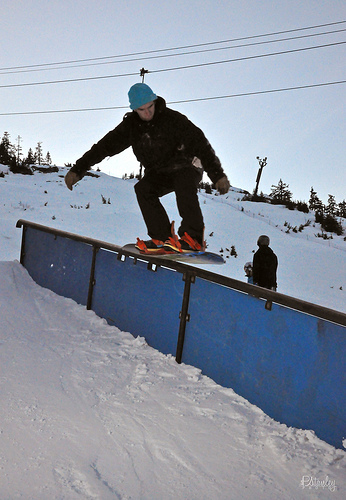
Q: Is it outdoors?
A: Yes, it is outdoors.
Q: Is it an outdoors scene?
A: Yes, it is outdoors.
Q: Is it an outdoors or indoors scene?
A: It is outdoors.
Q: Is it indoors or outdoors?
A: It is outdoors.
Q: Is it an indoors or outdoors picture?
A: It is outdoors.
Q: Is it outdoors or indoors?
A: It is outdoors.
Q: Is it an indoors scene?
A: No, it is outdoors.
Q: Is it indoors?
A: No, it is outdoors.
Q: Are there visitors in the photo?
A: No, there are no visitors.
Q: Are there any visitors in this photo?
A: No, there are no visitors.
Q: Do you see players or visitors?
A: No, there are no visitors or players.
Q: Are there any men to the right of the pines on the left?
A: Yes, there is a man to the right of the pines.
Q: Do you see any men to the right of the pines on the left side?
A: Yes, there is a man to the right of the pines.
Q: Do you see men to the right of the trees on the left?
A: Yes, there is a man to the right of the pines.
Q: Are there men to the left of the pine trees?
A: No, the man is to the right of the pine trees.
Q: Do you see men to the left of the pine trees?
A: No, the man is to the right of the pine trees.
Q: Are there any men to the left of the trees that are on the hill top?
A: No, the man is to the right of the pine trees.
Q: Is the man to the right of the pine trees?
A: Yes, the man is to the right of the pine trees.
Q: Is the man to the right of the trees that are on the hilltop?
A: Yes, the man is to the right of the pine trees.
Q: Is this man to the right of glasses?
A: No, the man is to the right of the pine trees.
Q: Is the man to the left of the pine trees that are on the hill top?
A: No, the man is to the right of the pine trees.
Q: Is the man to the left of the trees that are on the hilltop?
A: No, the man is to the right of the pine trees.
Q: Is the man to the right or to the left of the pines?
A: The man is to the right of the pines.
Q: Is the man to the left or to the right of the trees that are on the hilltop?
A: The man is to the right of the pines.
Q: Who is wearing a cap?
A: The man is wearing a cap.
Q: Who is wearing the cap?
A: The man is wearing a cap.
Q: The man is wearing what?
A: The man is wearing a cap.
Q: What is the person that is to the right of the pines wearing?
A: The man is wearing a cap.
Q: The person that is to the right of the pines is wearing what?
A: The man is wearing a cap.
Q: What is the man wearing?
A: The man is wearing a cap.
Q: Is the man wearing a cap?
A: Yes, the man is wearing a cap.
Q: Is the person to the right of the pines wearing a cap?
A: Yes, the man is wearing a cap.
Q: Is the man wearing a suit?
A: No, the man is wearing a cap.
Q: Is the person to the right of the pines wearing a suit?
A: No, the man is wearing a cap.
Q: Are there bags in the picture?
A: No, there are no bags.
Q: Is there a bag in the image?
A: No, there are no bags.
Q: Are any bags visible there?
A: No, there are no bags.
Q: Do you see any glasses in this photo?
A: No, there are no glasses.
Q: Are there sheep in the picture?
A: No, there are no sheep.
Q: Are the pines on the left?
A: Yes, the pines are on the left of the image.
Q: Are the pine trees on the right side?
A: No, the pine trees are on the left of the image.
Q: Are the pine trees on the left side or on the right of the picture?
A: The pine trees are on the left of the image.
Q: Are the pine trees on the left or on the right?
A: The pine trees are on the left of the image.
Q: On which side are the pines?
A: The pines are on the left of the image.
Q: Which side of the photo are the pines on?
A: The pines are on the left of the image.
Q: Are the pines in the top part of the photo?
A: Yes, the pines are in the top of the image.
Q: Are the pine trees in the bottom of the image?
A: No, the pine trees are in the top of the image.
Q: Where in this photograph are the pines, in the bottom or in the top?
A: The pines are in the top of the image.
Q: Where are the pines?
A: The pines are on the hilltop.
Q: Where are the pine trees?
A: The pines are on the hilltop.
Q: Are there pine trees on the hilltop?
A: Yes, there are pine trees on the hilltop.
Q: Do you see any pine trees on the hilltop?
A: Yes, there are pine trees on the hilltop.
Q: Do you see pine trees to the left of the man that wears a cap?
A: Yes, there are pine trees to the left of the man.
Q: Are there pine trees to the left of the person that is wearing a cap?
A: Yes, there are pine trees to the left of the man.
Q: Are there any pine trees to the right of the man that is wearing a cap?
A: No, the pine trees are to the left of the man.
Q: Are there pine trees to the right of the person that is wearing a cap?
A: No, the pine trees are to the left of the man.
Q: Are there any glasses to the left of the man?
A: No, there are pine trees to the left of the man.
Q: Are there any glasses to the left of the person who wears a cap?
A: No, there are pine trees to the left of the man.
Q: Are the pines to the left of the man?
A: Yes, the pines are to the left of the man.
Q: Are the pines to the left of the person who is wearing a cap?
A: Yes, the pines are to the left of the man.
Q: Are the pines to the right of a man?
A: No, the pines are to the left of a man.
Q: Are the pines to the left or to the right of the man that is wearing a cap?
A: The pines are to the left of the man.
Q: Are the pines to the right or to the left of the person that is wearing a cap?
A: The pines are to the left of the man.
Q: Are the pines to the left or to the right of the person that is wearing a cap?
A: The pines are to the left of the man.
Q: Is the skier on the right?
A: Yes, the skier is on the right of the image.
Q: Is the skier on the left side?
A: No, the skier is on the right of the image.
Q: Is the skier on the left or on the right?
A: The skier is on the right of the image.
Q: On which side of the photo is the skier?
A: The skier is on the right of the image.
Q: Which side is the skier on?
A: The skier is on the right of the image.